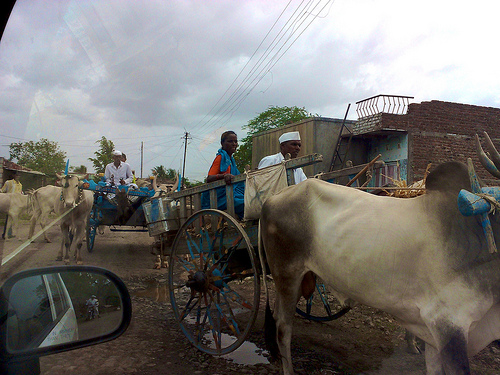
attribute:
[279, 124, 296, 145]
hat — white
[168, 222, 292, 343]
wheel — large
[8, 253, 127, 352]
mirror — in fore, side-view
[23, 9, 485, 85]
sky — cloudy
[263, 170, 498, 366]
animal — in fore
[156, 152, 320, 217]
railing — wooden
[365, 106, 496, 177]
wall — brick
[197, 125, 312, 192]
people — sitting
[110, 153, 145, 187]
man — in background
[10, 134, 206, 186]
trees — tall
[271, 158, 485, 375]
ox — bony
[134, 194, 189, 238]
pail — metal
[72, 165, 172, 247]
wagon — blue